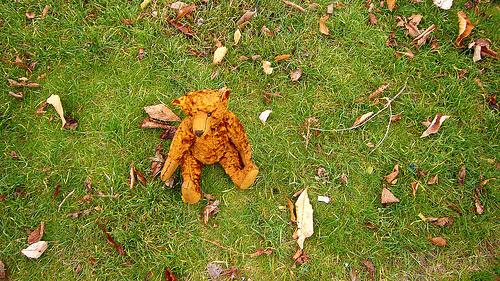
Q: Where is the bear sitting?
A: The ground.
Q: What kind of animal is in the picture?
A: Bear.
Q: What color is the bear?
A: Brown.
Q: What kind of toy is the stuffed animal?
A: Teddy bear.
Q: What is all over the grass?
A: Leaves.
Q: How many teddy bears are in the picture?
A: One.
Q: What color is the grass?
A: Green.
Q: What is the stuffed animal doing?
A: Sitting.